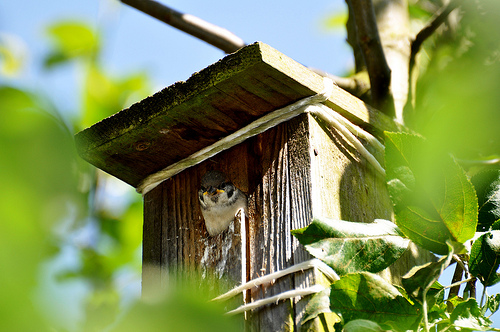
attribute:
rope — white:
[207, 252, 327, 310]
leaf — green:
[469, 230, 499, 284]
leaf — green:
[326, 274, 414, 330]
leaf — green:
[381, 130, 478, 254]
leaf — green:
[290, 217, 413, 269]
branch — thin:
[121, 2, 263, 57]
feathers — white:
[198, 174, 265, 222]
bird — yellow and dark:
[193, 173, 248, 282]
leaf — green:
[385, 129, 480, 260]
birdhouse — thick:
[58, 30, 449, 326]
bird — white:
[190, 168, 250, 238]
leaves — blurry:
[285, 96, 497, 311]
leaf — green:
[371, 119, 486, 254]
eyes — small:
[199, 181, 227, 191]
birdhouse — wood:
[88, 83, 349, 328]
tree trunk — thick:
[345, 5, 417, 119]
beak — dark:
[209, 186, 215, 200]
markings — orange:
[198, 181, 239, 203]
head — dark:
[195, 175, 235, 217]